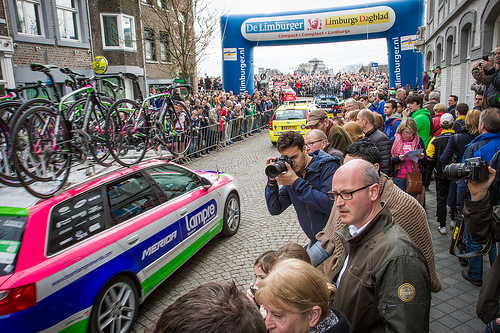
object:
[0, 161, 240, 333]
car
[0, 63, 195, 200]
bicycle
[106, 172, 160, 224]
window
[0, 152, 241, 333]
white car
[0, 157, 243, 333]
many colours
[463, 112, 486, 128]
ground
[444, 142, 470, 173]
ground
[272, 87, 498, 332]
roadside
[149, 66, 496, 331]
people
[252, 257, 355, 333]
person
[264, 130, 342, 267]
person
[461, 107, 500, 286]
person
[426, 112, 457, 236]
person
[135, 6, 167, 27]
wall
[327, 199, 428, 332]
coat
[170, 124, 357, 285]
road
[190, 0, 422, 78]
sky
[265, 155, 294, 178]
camera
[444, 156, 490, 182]
camera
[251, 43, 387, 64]
clouds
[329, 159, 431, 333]
man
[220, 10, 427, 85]
line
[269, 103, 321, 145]
car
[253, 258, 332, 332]
hair